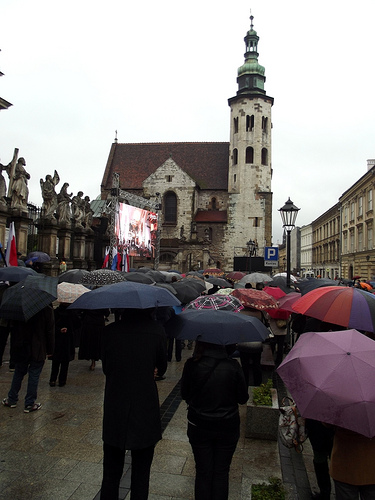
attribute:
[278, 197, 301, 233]
lamp — white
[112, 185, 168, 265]
screen — large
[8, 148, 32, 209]
statue — bronze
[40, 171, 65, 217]
statue — bronze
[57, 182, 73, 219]
statue — bronze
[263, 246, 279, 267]
sign — blue, white, metal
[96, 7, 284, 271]
building — old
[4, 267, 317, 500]
sidewalk — wet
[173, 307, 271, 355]
umbrella — black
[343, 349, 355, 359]
circle — black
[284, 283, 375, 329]
umbrella — multicolored, striped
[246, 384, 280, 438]
planter — stone, gray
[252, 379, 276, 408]
plant — green, small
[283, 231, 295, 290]
post — black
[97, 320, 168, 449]
jacket — black, long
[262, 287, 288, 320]
umbrella — pink, open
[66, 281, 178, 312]
umbrella — blue, open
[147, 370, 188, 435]
tiles — black, stone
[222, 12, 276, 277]
tower — large, stone